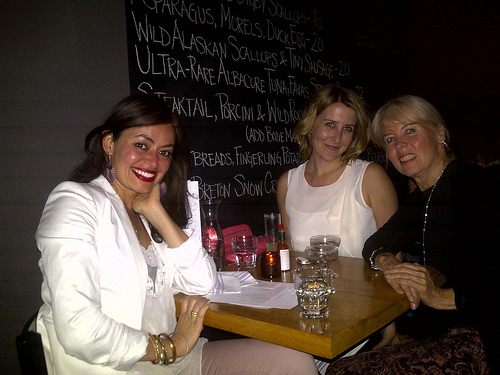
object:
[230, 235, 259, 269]
glasses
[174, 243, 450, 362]
table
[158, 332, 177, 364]
bracelet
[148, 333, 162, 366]
bracelet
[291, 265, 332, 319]
glasses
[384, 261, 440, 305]
hand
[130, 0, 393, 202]
menu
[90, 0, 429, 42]
top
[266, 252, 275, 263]
flame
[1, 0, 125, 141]
gray wall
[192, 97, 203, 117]
chalk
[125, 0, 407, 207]
blackboard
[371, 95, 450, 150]
hair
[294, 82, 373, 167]
hair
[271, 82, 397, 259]
woman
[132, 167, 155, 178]
teeth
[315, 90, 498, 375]
woman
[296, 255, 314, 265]
cellphone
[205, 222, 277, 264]
wallet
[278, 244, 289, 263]
sauce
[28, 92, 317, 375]
woman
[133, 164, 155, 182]
lipstick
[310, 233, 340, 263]
glass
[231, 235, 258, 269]
glass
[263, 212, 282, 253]
glass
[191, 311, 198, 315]
rings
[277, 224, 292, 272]
bottle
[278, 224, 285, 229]
cap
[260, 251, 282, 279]
holder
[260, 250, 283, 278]
candle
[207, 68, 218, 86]
chalk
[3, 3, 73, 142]
section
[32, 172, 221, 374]
jacket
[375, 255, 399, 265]
wrist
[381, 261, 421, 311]
hand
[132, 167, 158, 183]
lips